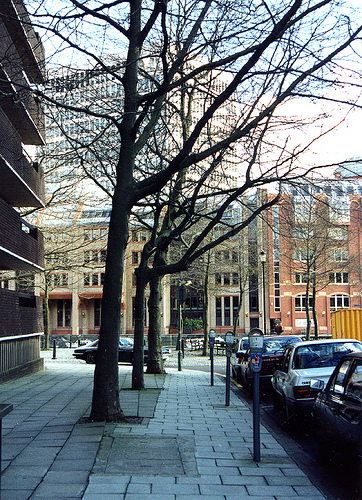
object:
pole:
[252, 372, 260, 462]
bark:
[103, 297, 114, 384]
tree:
[2, 1, 360, 426]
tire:
[86, 351, 96, 364]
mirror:
[308, 379, 324, 391]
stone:
[100, 436, 187, 478]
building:
[0, 0, 47, 362]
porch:
[0, 268, 46, 335]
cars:
[229, 335, 250, 380]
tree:
[147, 171, 271, 358]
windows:
[293, 292, 316, 313]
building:
[267, 191, 361, 341]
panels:
[103, 435, 185, 477]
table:
[212, 334, 226, 355]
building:
[48, 177, 265, 341]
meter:
[248, 327, 265, 463]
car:
[72, 336, 171, 366]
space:
[7, 7, 48, 360]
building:
[47, 57, 238, 195]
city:
[0, 0, 360, 499]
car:
[309, 350, 361, 479]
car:
[240, 335, 303, 400]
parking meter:
[223, 330, 236, 405]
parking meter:
[208, 329, 216, 387]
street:
[0, 331, 362, 500]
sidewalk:
[0, 362, 341, 500]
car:
[269, 338, 361, 430]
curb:
[213, 370, 340, 500]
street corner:
[53, 346, 227, 374]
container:
[330, 306, 361, 342]